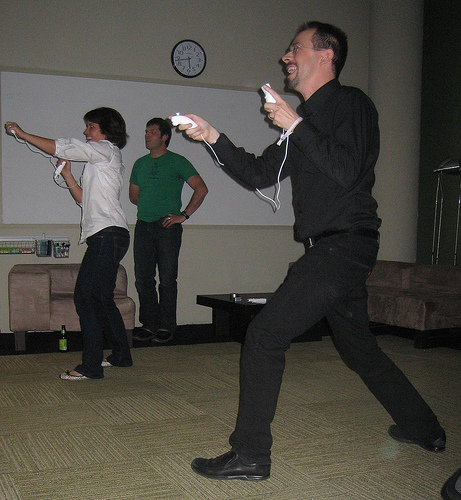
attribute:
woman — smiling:
[60, 96, 133, 167]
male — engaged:
[170, 21, 449, 480]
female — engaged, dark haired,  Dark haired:
[5, 106, 140, 380]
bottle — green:
[29, 315, 84, 354]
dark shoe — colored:
[386, 412, 431, 439]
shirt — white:
[54, 138, 131, 243]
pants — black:
[73, 225, 132, 379]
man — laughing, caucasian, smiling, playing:
[173, 10, 448, 484]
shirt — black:
[204, 77, 383, 244]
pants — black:
[228, 237, 442, 452]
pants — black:
[131, 218, 185, 333]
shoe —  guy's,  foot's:
[135, 289, 167, 344]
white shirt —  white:
[52, 136, 129, 242]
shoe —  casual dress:
[57, 368, 89, 381]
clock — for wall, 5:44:
[116, 34, 235, 85]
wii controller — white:
[164, 112, 224, 154]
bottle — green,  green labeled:
[56, 322, 70, 354]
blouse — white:
[36, 129, 121, 237]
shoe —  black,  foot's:
[189, 447, 273, 482]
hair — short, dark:
[79, 103, 134, 148]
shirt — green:
[121, 143, 204, 225]